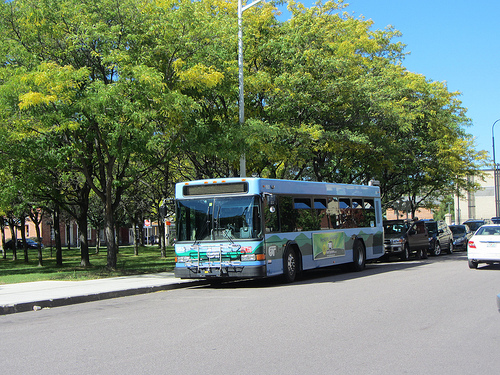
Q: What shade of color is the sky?
A: Blue.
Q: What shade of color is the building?
A: Gray.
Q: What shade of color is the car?
A: White.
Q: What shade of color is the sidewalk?
A: Gray.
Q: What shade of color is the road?
A: Gray.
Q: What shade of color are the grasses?
A: Green.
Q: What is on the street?
A: Bus.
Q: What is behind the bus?
A: Trees.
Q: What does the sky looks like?
A: Clear and blue.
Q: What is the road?
A: Asphalt.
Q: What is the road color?
A: Gray.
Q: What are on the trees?
A: Leaves.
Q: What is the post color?
A: Silver.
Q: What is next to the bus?
A: Post.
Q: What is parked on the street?
A: Bus.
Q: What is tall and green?
A: Trees.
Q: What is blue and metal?
A: Bus.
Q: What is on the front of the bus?
A: Bike rack.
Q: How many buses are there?
A: One.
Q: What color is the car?
A: White.